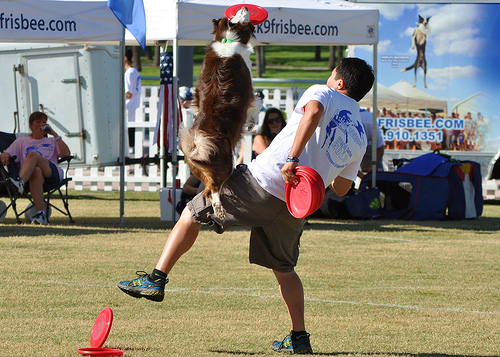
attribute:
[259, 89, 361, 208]
shirt — white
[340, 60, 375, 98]
hair — short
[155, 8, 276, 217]
dog — brown, jumping, white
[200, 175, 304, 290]
shorts — brown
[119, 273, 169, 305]
sneakers — blue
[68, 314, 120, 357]
frisbee — red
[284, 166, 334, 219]
frisbees — red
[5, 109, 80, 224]
woman — sitting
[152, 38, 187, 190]
flag — american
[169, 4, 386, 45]
banner — white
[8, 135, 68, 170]
shirt — pink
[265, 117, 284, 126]
sunglasses — dark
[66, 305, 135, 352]
frisbees — red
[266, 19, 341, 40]
letters — blue